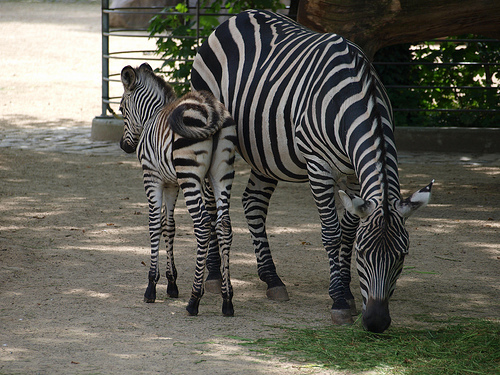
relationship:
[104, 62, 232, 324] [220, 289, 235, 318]
zebra has small hoof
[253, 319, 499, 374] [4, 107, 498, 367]
grass on ground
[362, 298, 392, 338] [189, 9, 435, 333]
nose of adult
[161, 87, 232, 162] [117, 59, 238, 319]
tail of zebra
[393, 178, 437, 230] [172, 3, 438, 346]
ear of zebra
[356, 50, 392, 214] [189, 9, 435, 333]
mane of adult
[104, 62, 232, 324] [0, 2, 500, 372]
zebra on ground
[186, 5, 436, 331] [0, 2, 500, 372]
zebras on ground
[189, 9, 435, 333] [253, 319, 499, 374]
adult eating grass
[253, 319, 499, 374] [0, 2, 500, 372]
grass on ground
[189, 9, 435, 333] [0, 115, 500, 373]
adult standing in dirt